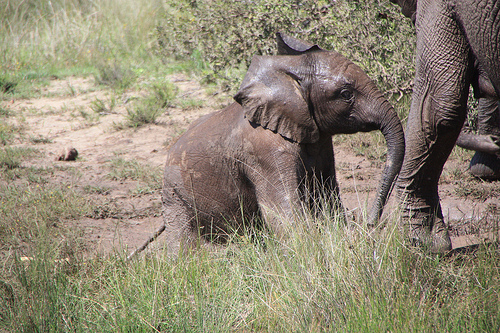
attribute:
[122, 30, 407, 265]
elephant — baby, wet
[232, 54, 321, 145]
ear — large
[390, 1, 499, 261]
elephant — large, adult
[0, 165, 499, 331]
grass — patchy, a small patch, tall, green, in foreground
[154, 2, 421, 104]
bush — in background, dry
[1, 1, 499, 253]
ground — brown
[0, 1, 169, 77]
grass — dry, green